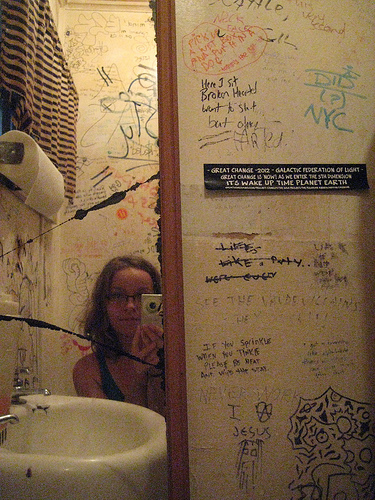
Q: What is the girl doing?
A: Taking a selfie.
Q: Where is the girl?
A: In the bathroom.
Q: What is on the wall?
A: Many words.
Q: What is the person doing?
A: Taking a picture.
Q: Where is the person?
A: Bathroom.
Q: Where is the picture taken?
A: Bathroom.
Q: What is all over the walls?
A: Graffiti.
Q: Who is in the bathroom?
A: A girl.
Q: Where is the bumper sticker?
A: On the wall.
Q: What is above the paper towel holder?
A: Curtain.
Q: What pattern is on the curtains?
A: Stripes.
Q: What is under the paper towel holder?
A: A sink.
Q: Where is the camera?
A: In the girl's hand.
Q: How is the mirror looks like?
A: Wood.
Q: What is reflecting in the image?
A: Girl.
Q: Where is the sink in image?
A: Bathroom.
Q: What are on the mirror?
A: Cracks.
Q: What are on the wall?
A: Black marker.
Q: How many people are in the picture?
A: One.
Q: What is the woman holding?
A: A camera.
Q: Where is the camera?
A: In the girl's hand.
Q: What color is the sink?
A: White.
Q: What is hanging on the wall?
A: Paper towels.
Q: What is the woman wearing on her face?
A: Glasses.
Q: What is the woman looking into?
A: A mirror.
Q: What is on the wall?
A: Writing.